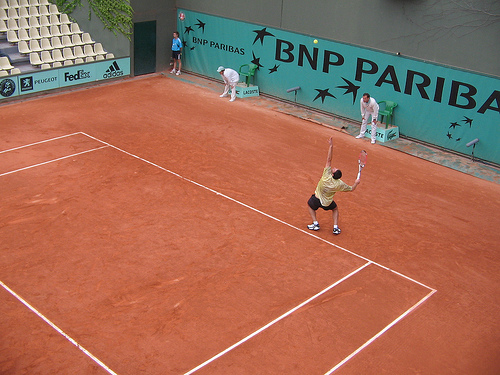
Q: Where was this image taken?
A: On a tennis court.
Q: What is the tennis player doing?
A: Serving the ball.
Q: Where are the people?
A: On the tennis court.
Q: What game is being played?
A: Tennis.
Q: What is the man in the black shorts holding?
A: A tennis racket.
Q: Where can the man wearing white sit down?
A: On the green chair.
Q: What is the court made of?
A: Clay.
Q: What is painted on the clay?
A: White lines.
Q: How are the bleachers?
A: Vacant.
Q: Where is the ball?
A: In the air.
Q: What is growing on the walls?
A: Vines.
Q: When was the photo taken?
A: During the daytime.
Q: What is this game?
A: Tennis.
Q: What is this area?
A: Tennis court.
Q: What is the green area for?
A: To bound the court.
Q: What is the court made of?
A: Clay.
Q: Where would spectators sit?
A: In the white seats.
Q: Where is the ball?
A: In the air.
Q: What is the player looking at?
A: The ball.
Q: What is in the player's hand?
A: Racket.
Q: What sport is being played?
A: Tennis.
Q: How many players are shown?
A: One.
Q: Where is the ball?
A: In the air.